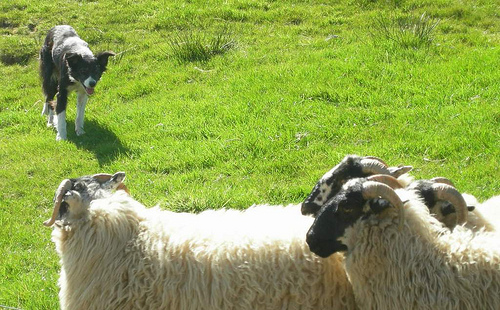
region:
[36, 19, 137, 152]
black and white dog with mouth open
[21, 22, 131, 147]
black and white dog standing on grass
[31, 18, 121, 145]
dog in field with mouth open watching sheep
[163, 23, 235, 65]
patch of grass that stands out in the field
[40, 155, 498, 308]
a group of sheep in field near dog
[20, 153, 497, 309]
a group of white sheep with horns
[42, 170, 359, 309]
a white and black sheep watching the dog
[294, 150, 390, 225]
a sheep showing partial black and white face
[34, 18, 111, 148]
a dog with white paws creeping up on sheep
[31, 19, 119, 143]
a dog with a black and white nose has its paws in grass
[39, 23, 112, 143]
a black and white sheep dog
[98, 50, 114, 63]
the black ear of a dog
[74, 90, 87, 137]
a white leg on a dog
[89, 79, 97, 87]
the black nose of a dog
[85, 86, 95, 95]
the pink tongue of a dog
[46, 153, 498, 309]
sheep behind herded by a dog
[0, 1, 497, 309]
a green grassy field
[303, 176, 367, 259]
the black face of a sheep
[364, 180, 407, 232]
the curving horn of a sheep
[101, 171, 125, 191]
the ear of a sheep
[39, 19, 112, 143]
black and white dog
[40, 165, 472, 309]
four sheep standing together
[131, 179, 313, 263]
sunlight on the sheep's back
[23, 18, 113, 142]
dog watching the sheep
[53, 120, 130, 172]
dog's shadow on the grass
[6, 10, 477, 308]
grass pasture sheep and dog are in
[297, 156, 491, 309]
two sheep with black faces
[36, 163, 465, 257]
horns of the sheep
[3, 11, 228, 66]
patches of weeds in the grass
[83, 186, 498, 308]
wooly fur of the sheep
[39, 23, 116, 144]
Dog standing in a field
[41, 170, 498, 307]
Sheep in a field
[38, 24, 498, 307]
Dog herding sheep in a field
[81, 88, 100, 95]
Tongue of dog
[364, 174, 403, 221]
Horns on ram's head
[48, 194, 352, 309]
Fleece coat of ram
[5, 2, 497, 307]
Grass covered field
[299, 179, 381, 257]
Black face of a ram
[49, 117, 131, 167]
Shadow of dog on ground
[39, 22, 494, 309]
Dog looking at rams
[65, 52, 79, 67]
The left ear of the dog.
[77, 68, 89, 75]
The left eye of the dog.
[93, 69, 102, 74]
The right eye of the dog.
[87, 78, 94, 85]
The nose of the dog.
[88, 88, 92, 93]
The tongue of the dog.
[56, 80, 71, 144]
The front left leg of the dog.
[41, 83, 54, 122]
The back leg of the dog.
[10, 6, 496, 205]
The pasture where the dog is standing.